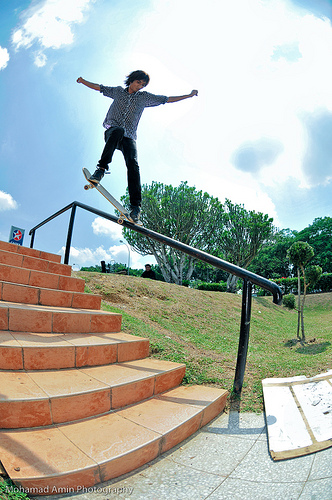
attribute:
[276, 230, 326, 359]
tree — small, skinny